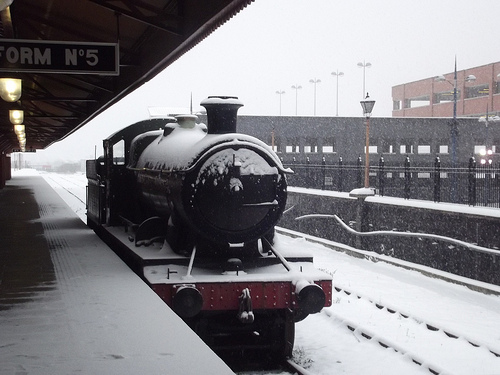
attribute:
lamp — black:
[356, 87, 376, 118]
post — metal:
[361, 121, 373, 188]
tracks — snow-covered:
[93, 213, 469, 360]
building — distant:
[384, 61, 498, 116]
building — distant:
[208, 111, 498, 191]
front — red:
[184, 282, 361, 321]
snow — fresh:
[5, 168, 499, 373]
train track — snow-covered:
[43, 171, 498, 373]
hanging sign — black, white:
[1, 34, 122, 82]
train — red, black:
[88, 104, 338, 359]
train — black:
[98, 103, 305, 358]